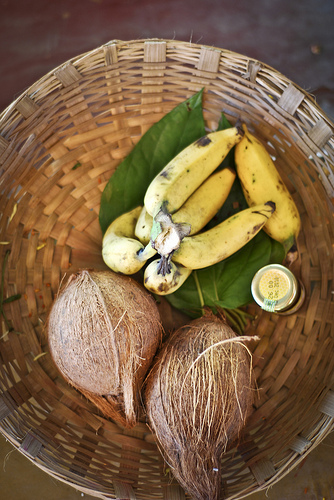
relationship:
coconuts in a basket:
[32, 261, 264, 482] [1, 31, 333, 306]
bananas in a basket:
[64, 136, 295, 275] [1, 31, 333, 306]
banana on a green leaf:
[229, 123, 313, 253] [101, 117, 180, 181]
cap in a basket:
[250, 262, 299, 312] [1, 31, 333, 306]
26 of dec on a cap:
[265, 275, 284, 304] [250, 262, 299, 312]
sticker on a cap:
[261, 297, 284, 313] [250, 262, 299, 312]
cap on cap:
[250, 262, 299, 312] [250, 262, 299, 312]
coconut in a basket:
[21, 259, 159, 412] [1, 31, 333, 306]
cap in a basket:
[248, 269, 295, 302] [1, 31, 333, 306]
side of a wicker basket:
[71, 75, 128, 115] [41, 43, 293, 158]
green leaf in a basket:
[101, 117, 180, 181] [1, 31, 333, 306]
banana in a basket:
[229, 123, 313, 253] [1, 31, 333, 306]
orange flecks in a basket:
[260, 5, 323, 57] [1, 31, 333, 306]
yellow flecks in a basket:
[10, 194, 60, 259] [1, 31, 333, 306]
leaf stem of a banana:
[119, 156, 145, 188] [229, 123, 313, 253]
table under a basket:
[224, 8, 308, 48] [1, 31, 333, 306]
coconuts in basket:
[32, 261, 264, 482] [1, 31, 333, 306]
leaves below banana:
[154, 125, 182, 148] [229, 123, 313, 253]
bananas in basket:
[64, 136, 295, 275] [1, 31, 333, 306]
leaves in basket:
[154, 125, 182, 148] [1, 31, 333, 306]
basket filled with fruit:
[1, 31, 333, 306] [41, 201, 241, 381]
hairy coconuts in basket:
[32, 261, 264, 482] [1, 31, 333, 306]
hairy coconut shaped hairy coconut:
[138, 307, 268, 500] [73, 289, 165, 384]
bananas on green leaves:
[64, 136, 295, 275] [116, 151, 256, 298]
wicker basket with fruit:
[41, 43, 293, 158] [41, 201, 241, 381]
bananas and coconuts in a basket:
[41, 201, 241, 381] [1, 31, 333, 306]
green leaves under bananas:
[116, 151, 256, 298] [64, 136, 295, 275]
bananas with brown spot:
[64, 136, 295, 275] [197, 136, 211, 150]